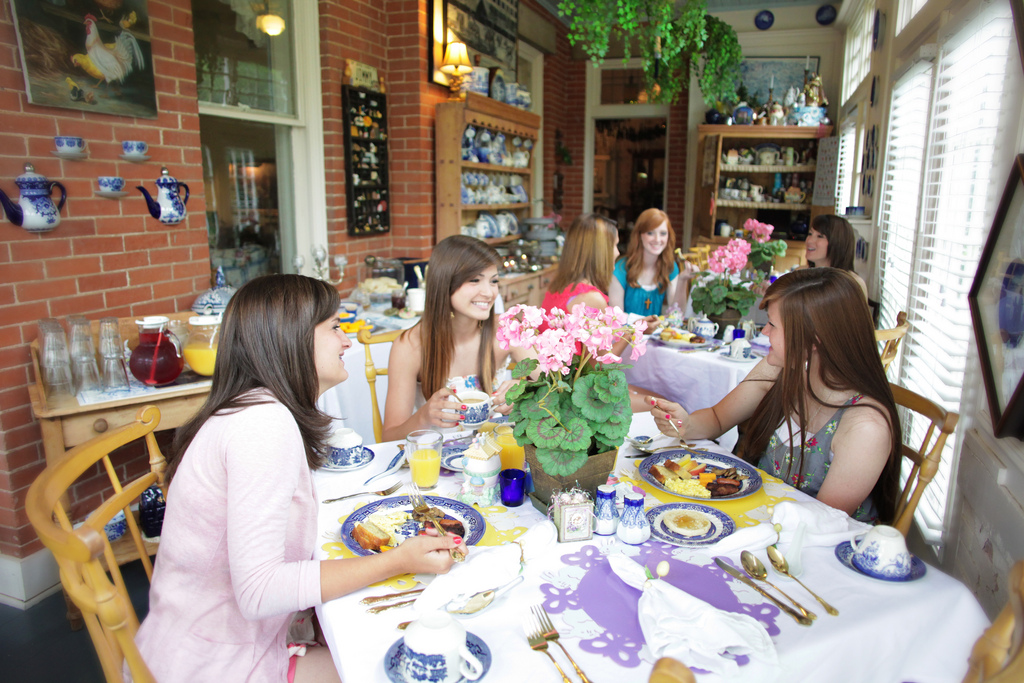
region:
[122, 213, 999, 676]
Three young women sitting around a table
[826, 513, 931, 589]
A cup on a saucer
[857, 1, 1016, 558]
White blinds are open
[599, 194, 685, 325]
A woman wearing a blue top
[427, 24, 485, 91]
A light is turned on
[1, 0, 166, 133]
A painting hanging on the wall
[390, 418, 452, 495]
Orange juice in a glass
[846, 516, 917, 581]
White and blue upside down tea cup.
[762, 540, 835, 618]
Gold spoon sitting on table.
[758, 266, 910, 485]
Girl has long brown hair.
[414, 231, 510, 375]
Girl has long brown hair.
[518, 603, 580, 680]
2 forks sitting on table.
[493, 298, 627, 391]
Pink flowers in center of table.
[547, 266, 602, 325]
Girl is wearing pink shirt.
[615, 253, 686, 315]
Girl wearing blue shirt.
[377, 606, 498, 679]
a cup on a saucer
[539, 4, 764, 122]
a green plant hanging from the ceiling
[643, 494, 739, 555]
an egg on a plate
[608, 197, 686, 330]
a girl in a blue shirt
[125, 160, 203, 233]
teapot decor hanging on the wall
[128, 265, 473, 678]
girl wearing a white shirt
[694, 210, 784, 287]
pink flowers on the table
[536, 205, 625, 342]
girl wearing a pink shirt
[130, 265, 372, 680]
Shoulder length brunette woman smiling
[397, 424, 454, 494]
Glass half filled with orange juice.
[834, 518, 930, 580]
An overturned tea cup sitting on a saucer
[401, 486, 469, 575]
A right hand holding a fork suspended midair.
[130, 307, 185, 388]
A filled pitcher with red liquid.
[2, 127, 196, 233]
A tea setting suspended on a brick wall.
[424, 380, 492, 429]
A right hand with red fingernail polish holding a cup.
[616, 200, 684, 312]
A strawberry haired woman with blue blouse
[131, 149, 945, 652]
a group of young women eating together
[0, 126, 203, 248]
dishes on a brick wall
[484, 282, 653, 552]
a pink flowered plant in a container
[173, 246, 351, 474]
woman has brown hair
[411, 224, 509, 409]
woman has brown hair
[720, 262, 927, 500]
woman has brown hair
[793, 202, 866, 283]
woman has brown hair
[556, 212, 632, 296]
woman has brown hair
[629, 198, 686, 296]
woman has red hair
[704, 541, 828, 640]
spoons on the table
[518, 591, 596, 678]
forks on the table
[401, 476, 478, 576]
woman holding a fork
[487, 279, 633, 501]
bouquet of flowers on the table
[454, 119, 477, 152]
nick knack on the wooden shelf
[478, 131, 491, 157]
nick knack on the wooden shelf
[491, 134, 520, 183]
nick knack on the wooden shelf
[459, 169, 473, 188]
nick knack on the wooden shelf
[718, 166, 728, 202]
nick knack on the wooden shelf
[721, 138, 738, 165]
nick knack on the wooden shelf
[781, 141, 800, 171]
nick knack on the wooden shelf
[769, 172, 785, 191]
nick knack on the wooden shelf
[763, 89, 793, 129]
nick knack on the wooden shelf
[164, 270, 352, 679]
a woman sitting at a table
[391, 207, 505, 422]
a woman sitting at a table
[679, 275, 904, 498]
a woman sitting at a table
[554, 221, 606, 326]
a woman sitting at a table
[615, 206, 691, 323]
a woman sitting at a table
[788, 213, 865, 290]
a woman sitting at a table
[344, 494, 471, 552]
a plate on a table